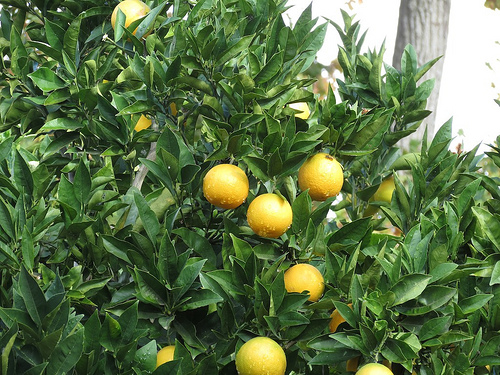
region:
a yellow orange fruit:
[303, 144, 342, 206]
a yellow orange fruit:
[249, 185, 290, 242]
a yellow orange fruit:
[197, 160, 252, 212]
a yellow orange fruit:
[278, 258, 324, 313]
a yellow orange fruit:
[231, 323, 292, 373]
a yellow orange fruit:
[111, 3, 165, 45]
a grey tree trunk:
[392, 0, 451, 203]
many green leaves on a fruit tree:
[5, 2, 497, 371]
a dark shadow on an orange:
[325, 148, 334, 164]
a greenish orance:
[230, 337, 291, 373]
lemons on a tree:
[196, 162, 253, 197]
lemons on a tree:
[239, 185, 296, 235]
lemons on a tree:
[262, 245, 349, 310]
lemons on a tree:
[233, 326, 293, 373]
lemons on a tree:
[275, 146, 345, 198]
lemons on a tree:
[345, 319, 397, 371]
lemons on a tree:
[350, 151, 432, 213]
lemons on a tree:
[99, 0, 179, 58]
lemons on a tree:
[112, 109, 179, 146]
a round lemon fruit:
[246, 192, 293, 239]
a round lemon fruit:
[297, 151, 342, 201]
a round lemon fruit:
[285, 263, 325, 303]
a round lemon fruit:
[235, 338, 286, 373]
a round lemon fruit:
[155, 344, 173, 370]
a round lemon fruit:
[354, 362, 389, 373]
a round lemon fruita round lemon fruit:
[109, 1, 149, 33]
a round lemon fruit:
[134, 101, 176, 130]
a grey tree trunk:
[395, 1, 448, 146]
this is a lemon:
[198, 150, 246, 205]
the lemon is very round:
[245, 191, 295, 231]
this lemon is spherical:
[190, 146, 255, 206]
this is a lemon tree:
[5, 7, 480, 368]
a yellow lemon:
[200, 148, 248, 212]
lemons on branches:
[7, 0, 464, 370]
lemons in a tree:
[71, 3, 453, 371]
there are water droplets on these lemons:
[197, 149, 326, 269]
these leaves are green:
[60, 183, 197, 336]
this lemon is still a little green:
[229, 324, 286, 374]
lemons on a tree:
[146, 103, 346, 260]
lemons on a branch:
[184, 141, 471, 367]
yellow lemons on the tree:
[179, 81, 496, 350]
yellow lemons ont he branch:
[172, 101, 429, 368]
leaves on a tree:
[146, 89, 416, 369]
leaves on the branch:
[118, 61, 394, 325]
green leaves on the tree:
[109, 68, 375, 290]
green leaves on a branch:
[89, 77, 383, 336]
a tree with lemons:
[126, 112, 493, 367]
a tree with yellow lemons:
[119, 115, 454, 362]